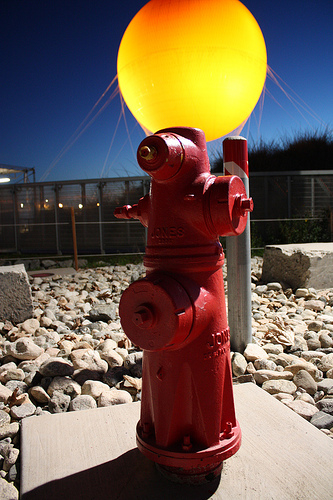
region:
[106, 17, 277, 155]
orange balloon in sky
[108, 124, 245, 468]
red hydrant on base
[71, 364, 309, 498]
base is brown wood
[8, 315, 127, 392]
stones around hydrant base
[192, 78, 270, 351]
red and white pole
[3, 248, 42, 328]
grey bricks on stones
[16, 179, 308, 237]
grey fence behind hydrant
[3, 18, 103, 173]
dark blue sky around balloon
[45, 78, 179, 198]
large lines hold balloon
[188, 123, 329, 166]
bushes are behind fence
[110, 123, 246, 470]
Red fire hydrant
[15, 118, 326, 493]
Red fire hydrant on a concrete slab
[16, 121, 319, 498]
Red fire hydrant sorrounded by rocks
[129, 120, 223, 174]
The top of a red fire hydrant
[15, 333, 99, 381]
Rocks on the ground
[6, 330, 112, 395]
Cream rocks on the ground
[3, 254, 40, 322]
Stone builder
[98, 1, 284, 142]
large orange baloon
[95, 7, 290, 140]
large orange baloon with ropes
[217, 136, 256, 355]
Red, white, and silver metal pole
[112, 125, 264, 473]
Red fire hydrant on a stone base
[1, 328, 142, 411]
Cluster of rocks and stone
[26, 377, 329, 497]
Stone base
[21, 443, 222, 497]
The shadow of a fire hydrant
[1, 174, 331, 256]
Metal fence behind a fire hydrant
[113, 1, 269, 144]
Yellow balloon behind a red fire hydrant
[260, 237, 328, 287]
Chunk of granite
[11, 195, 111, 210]
Group of lights behind the fence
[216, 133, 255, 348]
Red and gray steel pole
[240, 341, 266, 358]
Light pink and gray stone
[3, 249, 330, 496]
rocks around water pump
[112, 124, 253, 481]
water pump is in red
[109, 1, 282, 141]
yellow balloon behind water pump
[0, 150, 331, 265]
fence behind rocks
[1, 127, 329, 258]
trees behind fence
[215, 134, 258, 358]
silver pole behind red pump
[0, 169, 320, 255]
lights flashing through fences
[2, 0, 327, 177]
it is night and the sky is blue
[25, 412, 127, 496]
A piece of concrete on the ground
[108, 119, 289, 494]
The fire hydrant is on the ground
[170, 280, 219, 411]
The fire hydrant is red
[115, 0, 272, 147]
The hot air balloon is on the ground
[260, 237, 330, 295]
The concrete seating area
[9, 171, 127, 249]
The gate is made of metal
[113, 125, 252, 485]
the fire hydrant is red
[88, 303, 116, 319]
the rock is gray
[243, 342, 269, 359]
the rock is white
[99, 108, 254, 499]
a red fire hydrant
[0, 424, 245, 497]
the shadow of hydrant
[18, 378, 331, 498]
a grey concrete square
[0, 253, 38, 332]
a chuck of concrete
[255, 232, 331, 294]
a cunck of concrete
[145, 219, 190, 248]
the word Jones on hydrant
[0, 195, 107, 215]
the light are on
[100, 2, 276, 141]
a large yellow ball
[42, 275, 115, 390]
rocks on the ground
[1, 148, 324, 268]
a metal fence in back